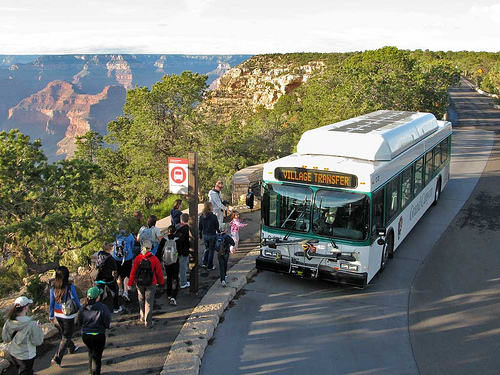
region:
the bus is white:
[202, 101, 387, 274]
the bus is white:
[264, 48, 381, 356]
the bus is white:
[271, 145, 443, 307]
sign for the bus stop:
[162, 153, 199, 202]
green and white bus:
[252, 112, 454, 286]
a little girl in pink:
[226, 210, 252, 257]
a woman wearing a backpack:
[127, 237, 165, 329]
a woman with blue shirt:
[43, 261, 83, 368]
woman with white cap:
[3, 291, 52, 371]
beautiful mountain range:
[6, 59, 134, 167]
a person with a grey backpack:
[155, 221, 191, 308]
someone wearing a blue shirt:
[106, 220, 138, 305]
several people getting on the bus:
[7, 160, 397, 367]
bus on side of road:
[263, 96, 458, 301]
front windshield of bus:
[262, 182, 369, 245]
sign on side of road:
[164, 155, 191, 197]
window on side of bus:
[394, 167, 411, 208]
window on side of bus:
[383, 182, 399, 215]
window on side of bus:
[364, 191, 389, 233]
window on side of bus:
[419, 152, 433, 182]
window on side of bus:
[432, 147, 443, 169]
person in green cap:
[82, 280, 109, 371]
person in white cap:
[0, 299, 43, 364]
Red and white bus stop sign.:
[159, 147, 189, 199]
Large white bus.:
[248, 77, 458, 299]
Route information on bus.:
[271, 157, 367, 196]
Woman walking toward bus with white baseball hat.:
[1, 296, 45, 373]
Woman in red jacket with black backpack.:
[123, 236, 175, 333]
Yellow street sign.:
[476, 65, 484, 77]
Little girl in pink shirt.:
[223, 205, 248, 254]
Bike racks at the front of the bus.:
[252, 225, 358, 274]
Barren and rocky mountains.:
[1, 53, 263, 150]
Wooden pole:
[179, 146, 202, 303]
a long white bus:
[252, 106, 457, 287]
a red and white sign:
[165, 157, 190, 197]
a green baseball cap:
[85, 285, 105, 300]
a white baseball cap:
[12, 292, 35, 309]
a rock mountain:
[5, 84, 126, 151]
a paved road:
[202, 77, 498, 374]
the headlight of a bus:
[338, 262, 364, 272]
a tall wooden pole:
[185, 149, 209, 295]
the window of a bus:
[315, 190, 369, 241]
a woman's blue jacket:
[73, 302, 112, 332]